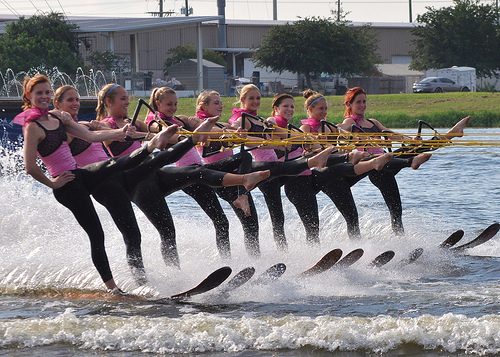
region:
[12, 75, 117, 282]
woman wearing pink scarf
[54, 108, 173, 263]
woman wearing pink scarf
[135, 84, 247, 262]
woman wearing pink scarf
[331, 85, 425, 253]
woman wearing pink scarf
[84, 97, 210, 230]
woman wearing pink scarf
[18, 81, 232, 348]
woman wearing pink scarf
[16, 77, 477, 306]
women wear pink and black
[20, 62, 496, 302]
a group of women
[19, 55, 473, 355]
a group of women water skiing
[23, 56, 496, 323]
a group of performers on waterskis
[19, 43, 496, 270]
nine women together on waterskis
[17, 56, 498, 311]
the women all have one foot lifted and one on a ski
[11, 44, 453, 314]
the women all wear pink and black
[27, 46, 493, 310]
the nine women are holding onto a rope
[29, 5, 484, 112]
a building on the shore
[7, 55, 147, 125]
a water fountain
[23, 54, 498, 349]
a group of women doing tricks on the water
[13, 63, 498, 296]
There's nine girls waterskiing.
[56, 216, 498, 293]
There's nine waterskis in the water.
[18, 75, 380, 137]
Nine girls are smiling.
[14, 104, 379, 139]
Nine girls wearing pink scarves.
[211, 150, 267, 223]
One girl has her knee bent.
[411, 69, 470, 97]
Silver car in background.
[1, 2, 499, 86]
Trees in background are green.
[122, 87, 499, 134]
The grass is green.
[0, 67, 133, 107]
Water is spitting out of fountain behind girls.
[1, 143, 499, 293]
The girl's are making a big splash.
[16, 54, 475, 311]
Ten women water skiing.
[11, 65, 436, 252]
Ten women dressed in pink and black.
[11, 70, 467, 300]
Ten women standing on one leg.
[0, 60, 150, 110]
Water fountain spraying water in arcs.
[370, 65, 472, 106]
Sports car parked on a street.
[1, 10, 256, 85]
Large protective cover made of metal.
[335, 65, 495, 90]
Wooden fence.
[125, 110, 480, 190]
Ten bare feet.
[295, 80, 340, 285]
Water skiing woman with blue headband.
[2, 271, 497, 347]
Wake from speed boat.